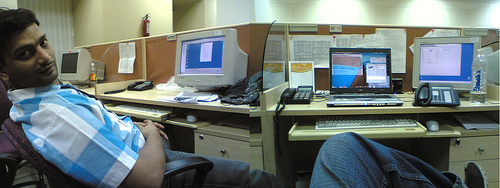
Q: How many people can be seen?
A: Two.